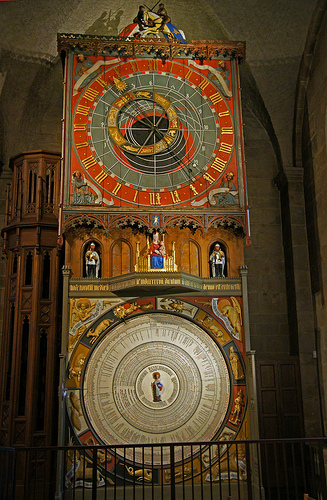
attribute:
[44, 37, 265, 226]
clock — old 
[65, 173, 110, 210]
clock — red , grey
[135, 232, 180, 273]
throne — gilded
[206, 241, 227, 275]
statue — small 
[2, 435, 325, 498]
fence — black 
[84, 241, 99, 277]
figurine — small 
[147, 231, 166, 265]
figurine — small 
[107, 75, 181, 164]
ring — gold 